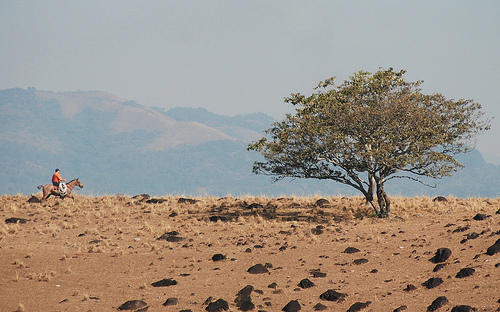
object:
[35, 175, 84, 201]
horse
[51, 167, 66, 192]
rider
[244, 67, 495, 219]
tree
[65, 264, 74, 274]
grass patch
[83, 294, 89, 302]
grass patch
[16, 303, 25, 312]
grass patch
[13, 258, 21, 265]
grass patch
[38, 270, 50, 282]
grass patch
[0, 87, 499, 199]
mountain range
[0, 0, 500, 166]
sky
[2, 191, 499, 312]
ground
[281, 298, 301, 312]
rock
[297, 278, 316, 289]
rock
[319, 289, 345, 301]
rock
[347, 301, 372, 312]
rock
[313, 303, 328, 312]
rock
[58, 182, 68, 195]
rope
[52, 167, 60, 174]
head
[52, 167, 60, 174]
hat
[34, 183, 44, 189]
tail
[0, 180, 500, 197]
horizon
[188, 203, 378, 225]
shadow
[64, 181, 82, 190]
reins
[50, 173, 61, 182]
shirt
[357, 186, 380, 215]
trunk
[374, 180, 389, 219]
trunk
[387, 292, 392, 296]
rock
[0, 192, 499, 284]
grassy area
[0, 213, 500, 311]
sandy area